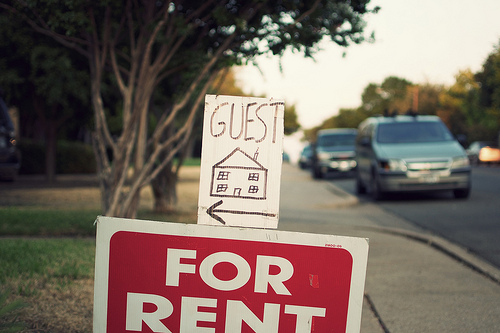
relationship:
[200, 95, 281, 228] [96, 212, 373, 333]
drawing near another rent sign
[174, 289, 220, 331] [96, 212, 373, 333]
letter on rent sign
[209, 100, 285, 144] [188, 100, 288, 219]
word written on paper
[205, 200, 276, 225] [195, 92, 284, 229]
arrow drawn on paper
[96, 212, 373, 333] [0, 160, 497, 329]
rent sign on ground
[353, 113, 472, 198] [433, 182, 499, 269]
car driving down road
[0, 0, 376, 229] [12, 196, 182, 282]
tree in ground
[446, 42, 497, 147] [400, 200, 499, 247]
trees across road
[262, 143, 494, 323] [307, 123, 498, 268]
sidewalk curving around road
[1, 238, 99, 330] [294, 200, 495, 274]
grasslands next to curb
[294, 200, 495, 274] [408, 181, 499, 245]
curb of street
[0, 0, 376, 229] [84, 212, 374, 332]
tree behind rent signs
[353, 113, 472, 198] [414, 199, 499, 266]
car parked on street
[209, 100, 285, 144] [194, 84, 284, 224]
word on sign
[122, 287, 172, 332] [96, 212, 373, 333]
letter on rent sign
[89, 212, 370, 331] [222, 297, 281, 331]
letter n on sign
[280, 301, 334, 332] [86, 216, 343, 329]
letter t on rent sign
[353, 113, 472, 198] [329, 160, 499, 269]
car parked along street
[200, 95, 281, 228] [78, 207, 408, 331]
drawing over sign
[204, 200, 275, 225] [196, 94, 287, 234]
arrow on sign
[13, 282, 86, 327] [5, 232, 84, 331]
dried grass on lawn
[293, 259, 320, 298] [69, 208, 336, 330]
scar on sign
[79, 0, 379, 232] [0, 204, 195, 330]
tree in yard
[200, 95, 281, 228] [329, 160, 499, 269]
drawing next to street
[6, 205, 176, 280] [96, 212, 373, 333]
grass behind rent sign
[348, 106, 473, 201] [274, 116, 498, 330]
car parked on street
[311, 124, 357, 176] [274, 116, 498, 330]
car parked on street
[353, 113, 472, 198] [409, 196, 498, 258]
car parked on street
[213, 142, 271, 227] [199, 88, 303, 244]
drawing on sign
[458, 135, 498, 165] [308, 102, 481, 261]
car parked on road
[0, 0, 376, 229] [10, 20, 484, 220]
tree in background